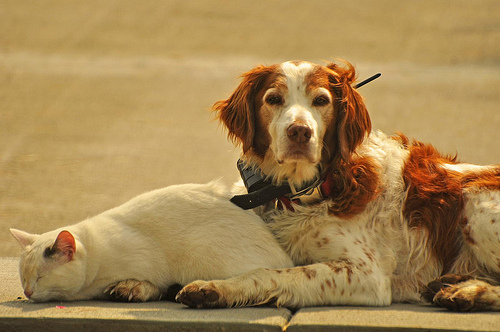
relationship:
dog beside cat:
[225, 30, 471, 314] [3, 182, 216, 291]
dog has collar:
[225, 30, 471, 314] [230, 160, 349, 237]